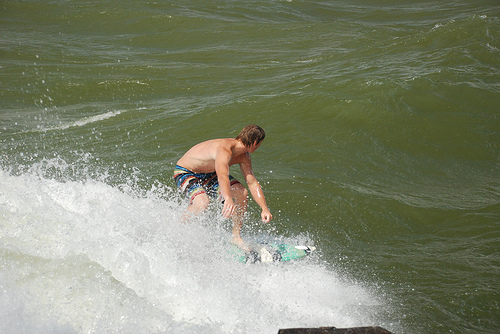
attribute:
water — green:
[293, 114, 421, 229]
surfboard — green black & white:
[225, 240, 317, 267]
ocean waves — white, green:
[2, 1, 497, 332]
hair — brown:
[235, 124, 265, 149]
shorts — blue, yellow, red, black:
[167, 168, 240, 206]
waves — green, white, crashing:
[2, 158, 399, 329]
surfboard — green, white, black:
[281, 245, 320, 259]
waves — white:
[10, 12, 496, 122]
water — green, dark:
[2, 4, 491, 331]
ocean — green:
[98, 17, 464, 137]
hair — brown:
[233, 123, 265, 144]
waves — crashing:
[373, 3, 498, 122]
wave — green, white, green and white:
[2, 147, 411, 329]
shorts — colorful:
[174, 161, 241, 206]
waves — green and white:
[170, 10, 499, 297]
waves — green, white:
[45, 36, 385, 298]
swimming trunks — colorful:
[171, 168, 245, 195]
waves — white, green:
[76, 208, 211, 273]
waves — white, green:
[4, 79, 174, 208]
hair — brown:
[236, 123, 273, 148]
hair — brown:
[243, 121, 264, 136]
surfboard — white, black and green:
[230, 242, 330, 264]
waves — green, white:
[9, 142, 389, 331]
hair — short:
[235, 124, 266, 144]